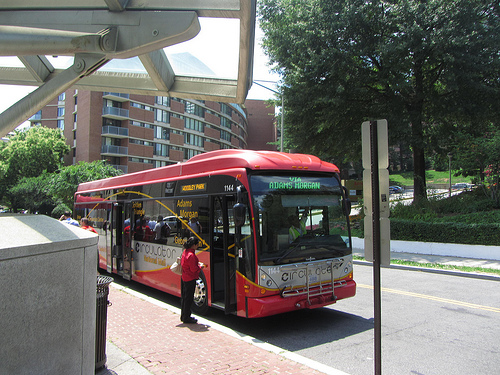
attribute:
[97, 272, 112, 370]
trash bin — black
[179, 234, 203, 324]
person — standing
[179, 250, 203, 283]
shirt — red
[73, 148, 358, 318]
bus — red, white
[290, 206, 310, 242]
driver — male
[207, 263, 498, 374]
street — gray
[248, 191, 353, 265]
windshield — large, glass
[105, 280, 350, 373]
sidewalk — brick, red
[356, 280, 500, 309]
line — yellow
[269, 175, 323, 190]
word — green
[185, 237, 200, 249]
hair — black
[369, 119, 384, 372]
pole — green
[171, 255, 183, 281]
purse — white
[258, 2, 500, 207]
tree — tall, green, brown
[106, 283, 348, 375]
side — walk